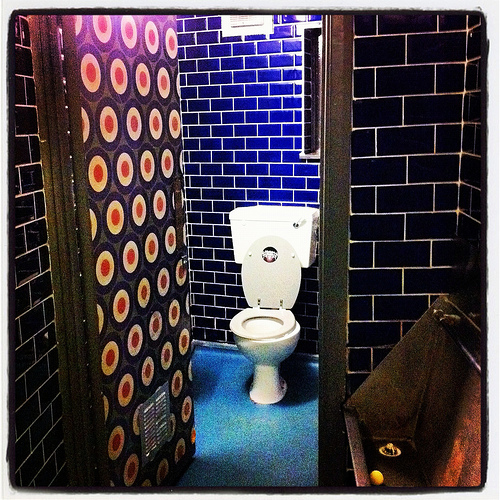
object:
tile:
[212, 176, 233, 189]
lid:
[241, 235, 302, 308]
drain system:
[380, 441, 402, 456]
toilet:
[227, 205, 320, 405]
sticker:
[262, 248, 279, 263]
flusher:
[292, 222, 299, 229]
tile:
[233, 98, 259, 109]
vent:
[140, 380, 168, 469]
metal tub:
[342, 294, 482, 487]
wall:
[346, 11, 487, 356]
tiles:
[354, 35, 405, 66]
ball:
[368, 468, 388, 487]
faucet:
[433, 309, 461, 326]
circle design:
[150, 181, 169, 228]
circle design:
[138, 143, 157, 189]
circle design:
[163, 218, 178, 261]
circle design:
[143, 225, 162, 270]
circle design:
[119, 232, 142, 281]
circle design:
[123, 98, 145, 149]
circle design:
[147, 100, 165, 147]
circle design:
[132, 54, 153, 104]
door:
[61, 12, 196, 488]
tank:
[229, 205, 321, 268]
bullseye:
[144, 158, 152, 174]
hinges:
[280, 300, 286, 311]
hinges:
[253, 299, 260, 309]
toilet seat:
[227, 306, 296, 339]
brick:
[218, 55, 245, 68]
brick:
[282, 97, 302, 108]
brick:
[210, 98, 233, 111]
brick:
[223, 138, 246, 150]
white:
[219, 15, 276, 39]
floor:
[174, 345, 319, 487]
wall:
[179, 20, 316, 350]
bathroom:
[71, 13, 322, 487]